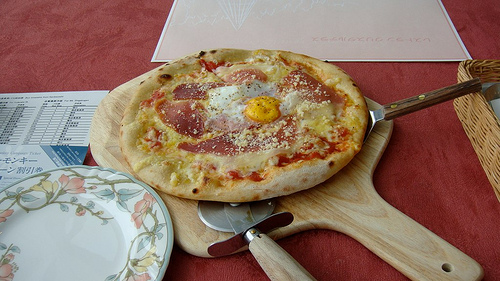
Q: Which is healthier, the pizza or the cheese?
A: The cheese is healthier than the pizza.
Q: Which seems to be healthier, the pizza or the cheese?
A: The cheese is healthier than the pizza.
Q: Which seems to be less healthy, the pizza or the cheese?
A: The pizza is less healthy than the cheese.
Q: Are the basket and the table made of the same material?
A: Yes, both the basket and the table are made of wood.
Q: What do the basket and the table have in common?
A: The material, both the basket and the table are wooden.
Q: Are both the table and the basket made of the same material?
A: Yes, both the table and the basket are made of wood.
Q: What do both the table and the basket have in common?
A: The material, both the table and the basket are wooden.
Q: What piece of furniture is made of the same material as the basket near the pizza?
A: The table is made of the same material as the basket.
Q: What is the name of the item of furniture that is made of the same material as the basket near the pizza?
A: The piece of furniture is a table.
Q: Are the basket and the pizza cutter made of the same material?
A: No, the basket is made of wood and the pizza cutter is made of metal.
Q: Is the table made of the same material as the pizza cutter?
A: No, the table is made of wood and the pizza cutter is made of metal.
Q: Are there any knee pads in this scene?
A: No, there are no knee pads.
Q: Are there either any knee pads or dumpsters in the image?
A: No, there are no knee pads or dumpsters.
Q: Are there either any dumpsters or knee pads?
A: No, there are no knee pads or dumpsters.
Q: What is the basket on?
A: The basket is on the table.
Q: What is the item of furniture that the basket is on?
A: The piece of furniture is a table.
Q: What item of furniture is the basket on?
A: The basket is on the table.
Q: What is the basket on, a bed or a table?
A: The basket is on a table.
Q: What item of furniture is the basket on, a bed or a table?
A: The basket is on a table.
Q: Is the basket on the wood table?
A: Yes, the basket is on the table.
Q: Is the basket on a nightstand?
A: No, the basket is on the table.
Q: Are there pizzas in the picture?
A: Yes, there is a pizza.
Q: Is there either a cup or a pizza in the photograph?
A: Yes, there is a pizza.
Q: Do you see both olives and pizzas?
A: No, there is a pizza but no olives.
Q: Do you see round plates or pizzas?
A: Yes, there is a round pizza.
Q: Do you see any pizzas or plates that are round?
A: Yes, the pizza is round.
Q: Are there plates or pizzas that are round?
A: Yes, the pizza is round.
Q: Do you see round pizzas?
A: Yes, there is a round pizza.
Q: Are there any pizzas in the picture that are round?
A: Yes, there is a pizza that is round.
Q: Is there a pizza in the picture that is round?
A: Yes, there is a pizza that is round.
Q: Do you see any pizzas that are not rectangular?
A: Yes, there is a round pizza.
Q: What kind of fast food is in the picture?
A: The fast food is a pizza.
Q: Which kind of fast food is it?
A: The food is a pizza.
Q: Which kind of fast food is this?
A: This is a pizza.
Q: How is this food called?
A: This is a pizza.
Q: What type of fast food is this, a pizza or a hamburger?
A: This is a pizza.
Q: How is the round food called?
A: The food is a pizza.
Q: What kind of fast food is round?
A: The fast food is a pizza.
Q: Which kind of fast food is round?
A: The fast food is a pizza.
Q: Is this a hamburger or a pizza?
A: This is a pizza.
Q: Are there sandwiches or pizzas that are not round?
A: No, there is a pizza but it is round.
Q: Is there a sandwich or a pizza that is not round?
A: No, there is a pizza but it is round.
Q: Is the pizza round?
A: Yes, the pizza is round.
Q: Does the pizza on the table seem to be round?
A: Yes, the pizza is round.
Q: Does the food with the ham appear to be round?
A: Yes, the pizza is round.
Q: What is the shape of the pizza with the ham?
A: The pizza is round.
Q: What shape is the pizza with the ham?
A: The pizza is round.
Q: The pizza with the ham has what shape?
A: The pizza is round.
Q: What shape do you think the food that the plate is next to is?
A: The pizza is round.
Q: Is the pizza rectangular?
A: No, the pizza is round.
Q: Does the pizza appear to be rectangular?
A: No, the pizza is round.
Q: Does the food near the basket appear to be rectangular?
A: No, the pizza is round.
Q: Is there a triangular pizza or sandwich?
A: No, there is a pizza but it is round.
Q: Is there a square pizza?
A: No, there is a pizza but it is round.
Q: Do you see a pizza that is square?
A: No, there is a pizza but it is round.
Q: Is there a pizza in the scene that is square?
A: No, there is a pizza but it is round.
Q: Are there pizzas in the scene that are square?
A: No, there is a pizza but it is round.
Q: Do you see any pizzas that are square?
A: No, there is a pizza but it is round.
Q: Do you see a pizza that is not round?
A: No, there is a pizza but it is round.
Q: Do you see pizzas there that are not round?
A: No, there is a pizza but it is round.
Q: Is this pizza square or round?
A: The pizza is round.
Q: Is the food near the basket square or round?
A: The pizza is round.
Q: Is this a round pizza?
A: Yes, this is a round pizza.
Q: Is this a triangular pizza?
A: No, this is a round pizza.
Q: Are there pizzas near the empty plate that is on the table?
A: Yes, there is a pizza near the plate.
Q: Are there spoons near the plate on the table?
A: No, there is a pizza near the plate.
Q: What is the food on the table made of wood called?
A: The food is a pizza.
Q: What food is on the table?
A: The food is a pizza.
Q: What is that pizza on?
A: The pizza is on the table.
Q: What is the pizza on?
A: The pizza is on the table.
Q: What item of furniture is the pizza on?
A: The pizza is on the table.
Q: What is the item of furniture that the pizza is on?
A: The piece of furniture is a table.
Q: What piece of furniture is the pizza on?
A: The pizza is on the table.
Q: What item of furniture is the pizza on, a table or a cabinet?
A: The pizza is on a table.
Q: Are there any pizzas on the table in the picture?
A: Yes, there is a pizza on the table.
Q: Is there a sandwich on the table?
A: No, there is a pizza on the table.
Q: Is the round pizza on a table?
A: Yes, the pizza is on a table.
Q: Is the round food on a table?
A: Yes, the pizza is on a table.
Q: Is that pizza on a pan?
A: No, the pizza is on a table.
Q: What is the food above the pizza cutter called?
A: The food is a pizza.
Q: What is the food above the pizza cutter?
A: The food is a pizza.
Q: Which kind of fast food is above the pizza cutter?
A: The food is a pizza.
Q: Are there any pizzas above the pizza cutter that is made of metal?
A: Yes, there is a pizza above the pizza cutter.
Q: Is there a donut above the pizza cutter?
A: No, there is a pizza above the pizza cutter.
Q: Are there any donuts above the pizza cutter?
A: No, there is a pizza above the pizza cutter.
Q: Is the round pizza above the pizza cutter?
A: Yes, the pizza is above the pizza cutter.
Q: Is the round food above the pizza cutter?
A: Yes, the pizza is above the pizza cutter.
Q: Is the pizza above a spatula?
A: No, the pizza is above the pizza cutter.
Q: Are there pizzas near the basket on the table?
A: Yes, there is a pizza near the basket.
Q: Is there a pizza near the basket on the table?
A: Yes, there is a pizza near the basket.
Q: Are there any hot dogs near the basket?
A: No, there is a pizza near the basket.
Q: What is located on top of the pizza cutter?
A: The pizza is on top of the pizza cutter.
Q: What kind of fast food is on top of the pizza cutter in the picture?
A: The food is a pizza.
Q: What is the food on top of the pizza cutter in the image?
A: The food is a pizza.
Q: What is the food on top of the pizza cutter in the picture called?
A: The food is a pizza.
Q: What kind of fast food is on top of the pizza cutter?
A: The food is a pizza.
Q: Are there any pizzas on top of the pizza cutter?
A: Yes, there is a pizza on top of the pizza cutter.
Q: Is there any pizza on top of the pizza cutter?
A: Yes, there is a pizza on top of the pizza cutter.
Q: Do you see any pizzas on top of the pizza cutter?
A: Yes, there is a pizza on top of the pizza cutter.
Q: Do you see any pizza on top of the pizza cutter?
A: Yes, there is a pizza on top of the pizza cutter.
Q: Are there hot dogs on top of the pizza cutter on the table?
A: No, there is a pizza on top of the pizza cutter.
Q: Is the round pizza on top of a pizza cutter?
A: Yes, the pizza is on top of a pizza cutter.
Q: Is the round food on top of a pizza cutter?
A: Yes, the pizza is on top of a pizza cutter.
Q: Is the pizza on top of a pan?
A: No, the pizza is on top of a pizza cutter.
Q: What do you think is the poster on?
A: The poster is on the table.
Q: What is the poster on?
A: The poster is on the table.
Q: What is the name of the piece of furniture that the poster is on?
A: The piece of furniture is a table.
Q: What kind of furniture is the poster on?
A: The poster is on the table.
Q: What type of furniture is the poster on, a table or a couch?
A: The poster is on a table.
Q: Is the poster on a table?
A: Yes, the poster is on a table.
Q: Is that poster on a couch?
A: No, the poster is on a table.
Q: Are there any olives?
A: No, there are no olives.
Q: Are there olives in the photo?
A: No, there are no olives.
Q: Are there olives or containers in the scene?
A: No, there are no olives or containers.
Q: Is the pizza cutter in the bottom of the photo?
A: Yes, the pizza cutter is in the bottom of the image.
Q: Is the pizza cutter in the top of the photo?
A: No, the pizza cutter is in the bottom of the image.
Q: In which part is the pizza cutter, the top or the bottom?
A: The pizza cutter is in the bottom of the image.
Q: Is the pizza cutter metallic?
A: Yes, the pizza cutter is metallic.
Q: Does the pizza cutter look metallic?
A: Yes, the pizza cutter is metallic.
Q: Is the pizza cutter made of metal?
A: Yes, the pizza cutter is made of metal.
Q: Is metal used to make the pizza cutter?
A: Yes, the pizza cutter is made of metal.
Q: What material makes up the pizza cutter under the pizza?
A: The pizza cutter is made of metal.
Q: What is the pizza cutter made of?
A: The pizza cutter is made of metal.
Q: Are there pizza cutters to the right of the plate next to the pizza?
A: Yes, there is a pizza cutter to the right of the plate.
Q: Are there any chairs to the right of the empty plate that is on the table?
A: No, there is a pizza cutter to the right of the plate.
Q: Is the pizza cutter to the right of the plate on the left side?
A: Yes, the pizza cutter is to the right of the plate.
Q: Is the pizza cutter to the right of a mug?
A: No, the pizza cutter is to the right of the plate.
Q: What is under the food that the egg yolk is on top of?
A: The pizza cutter is under the pizza.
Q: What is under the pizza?
A: The pizza cutter is under the pizza.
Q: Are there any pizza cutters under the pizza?
A: Yes, there is a pizza cutter under the pizza.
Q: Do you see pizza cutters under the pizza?
A: Yes, there is a pizza cutter under the pizza.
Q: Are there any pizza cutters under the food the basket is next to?
A: Yes, there is a pizza cutter under the pizza.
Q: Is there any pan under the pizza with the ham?
A: No, there is a pizza cutter under the pizza.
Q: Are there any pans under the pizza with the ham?
A: No, there is a pizza cutter under the pizza.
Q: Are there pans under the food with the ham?
A: No, there is a pizza cutter under the pizza.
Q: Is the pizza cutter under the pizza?
A: Yes, the pizza cutter is under the pizza.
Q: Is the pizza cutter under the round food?
A: Yes, the pizza cutter is under the pizza.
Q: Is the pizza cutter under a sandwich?
A: No, the pizza cutter is under the pizza.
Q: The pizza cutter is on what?
A: The pizza cutter is on the table.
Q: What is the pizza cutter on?
A: The pizza cutter is on the table.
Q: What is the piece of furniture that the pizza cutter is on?
A: The piece of furniture is a table.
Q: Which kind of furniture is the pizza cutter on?
A: The pizza cutter is on the table.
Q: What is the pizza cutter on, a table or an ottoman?
A: The pizza cutter is on a table.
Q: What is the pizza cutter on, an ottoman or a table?
A: The pizza cutter is on a table.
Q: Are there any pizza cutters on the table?
A: Yes, there is a pizza cutter on the table.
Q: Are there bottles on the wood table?
A: No, there is a pizza cutter on the table.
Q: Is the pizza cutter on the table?
A: Yes, the pizza cutter is on the table.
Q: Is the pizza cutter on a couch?
A: No, the pizza cutter is on the table.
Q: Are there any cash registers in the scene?
A: No, there are no cash registers.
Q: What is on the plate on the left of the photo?
A: The flowers are on the plate.